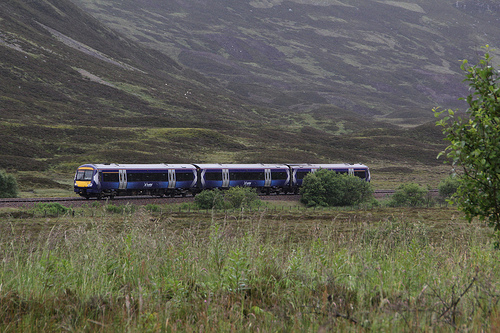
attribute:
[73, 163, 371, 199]
train — blue, white, passenger train, outdoor, long, moving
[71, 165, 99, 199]
front — yellow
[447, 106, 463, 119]
leaf — green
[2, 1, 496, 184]
hill — patchy, background, steep, brown, green, large, dirt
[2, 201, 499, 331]
grass — tall, green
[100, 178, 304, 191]
stripe — blue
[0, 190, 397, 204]
tracks — part empty, long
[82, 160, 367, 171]
roof — gray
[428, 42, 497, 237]
tree — green, small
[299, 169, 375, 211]
shrub — green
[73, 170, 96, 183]
window — large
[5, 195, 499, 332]
ground — weeds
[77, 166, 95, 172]
stripe — yellow